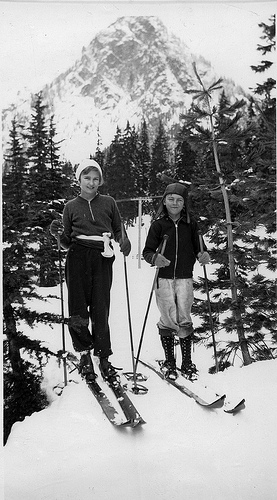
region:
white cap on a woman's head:
[75, 158, 104, 183]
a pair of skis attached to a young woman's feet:
[68, 351, 147, 430]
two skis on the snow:
[76, 367, 145, 434]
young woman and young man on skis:
[48, 142, 246, 430]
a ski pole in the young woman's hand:
[121, 211, 149, 395]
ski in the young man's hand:
[121, 232, 172, 382]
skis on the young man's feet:
[161, 356, 248, 416]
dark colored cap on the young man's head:
[147, 181, 193, 222]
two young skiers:
[48, 156, 247, 429]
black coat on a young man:
[141, 214, 209, 278]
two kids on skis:
[24, 140, 256, 428]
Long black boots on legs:
[146, 319, 214, 393]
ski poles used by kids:
[31, 220, 247, 416]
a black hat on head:
[144, 173, 211, 228]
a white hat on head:
[67, 155, 103, 178]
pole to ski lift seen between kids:
[124, 187, 156, 280]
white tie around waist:
[62, 220, 121, 258]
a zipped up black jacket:
[137, 206, 210, 274]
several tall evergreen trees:
[11, 91, 276, 295]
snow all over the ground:
[6, 206, 267, 495]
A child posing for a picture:
[147, 177, 226, 387]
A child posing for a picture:
[57, 160, 131, 377]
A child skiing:
[143, 177, 215, 378]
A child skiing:
[50, 150, 135, 380]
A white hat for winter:
[67, 158, 108, 177]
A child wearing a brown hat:
[158, 177, 192, 225]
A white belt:
[75, 230, 119, 256]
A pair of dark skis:
[61, 349, 150, 430]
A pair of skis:
[137, 352, 249, 414]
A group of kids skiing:
[49, 151, 225, 378]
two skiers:
[43, 157, 257, 435]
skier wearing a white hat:
[72, 154, 103, 183]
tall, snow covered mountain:
[18, 14, 252, 141]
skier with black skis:
[63, 347, 148, 433]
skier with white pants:
[151, 274, 193, 338]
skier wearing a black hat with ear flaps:
[146, 182, 193, 227]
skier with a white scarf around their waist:
[69, 229, 116, 262]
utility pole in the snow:
[126, 194, 154, 271]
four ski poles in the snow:
[49, 217, 218, 398]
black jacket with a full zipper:
[143, 214, 210, 278]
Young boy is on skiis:
[50, 149, 136, 450]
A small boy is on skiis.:
[140, 177, 240, 408]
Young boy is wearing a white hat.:
[69, 155, 104, 196]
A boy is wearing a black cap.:
[154, 179, 192, 219]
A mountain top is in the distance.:
[0, 9, 275, 118]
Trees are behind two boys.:
[103, 123, 163, 184]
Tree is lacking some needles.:
[197, 64, 263, 370]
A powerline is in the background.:
[128, 192, 153, 271]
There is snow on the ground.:
[3, 426, 274, 494]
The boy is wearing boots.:
[158, 321, 201, 381]